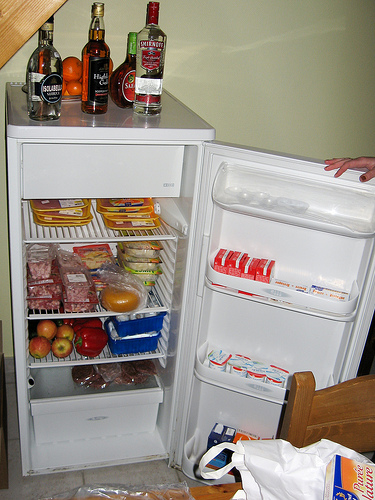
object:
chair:
[278, 370, 374, 454]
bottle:
[27, 14, 63, 122]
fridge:
[6, 81, 373, 477]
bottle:
[80, 2, 111, 115]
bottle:
[110, 31, 138, 109]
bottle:
[133, 1, 167, 116]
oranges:
[22, 56, 114, 101]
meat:
[31, 199, 95, 227]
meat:
[96, 197, 160, 230]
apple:
[29, 336, 52, 359]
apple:
[51, 337, 74, 359]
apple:
[37, 320, 60, 340]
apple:
[57, 324, 75, 342]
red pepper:
[74, 311, 108, 356]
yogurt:
[208, 347, 233, 372]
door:
[168, 138, 374, 486]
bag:
[199, 439, 375, 500]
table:
[86, 482, 244, 499]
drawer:
[29, 365, 164, 443]